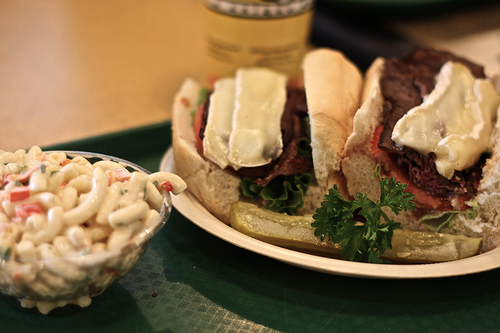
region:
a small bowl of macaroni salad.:
[2, 147, 179, 313]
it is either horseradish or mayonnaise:
[209, 73, 276, 171]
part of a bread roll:
[306, 51, 383, 208]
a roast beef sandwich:
[351, 48, 491, 284]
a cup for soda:
[198, 4, 304, 79]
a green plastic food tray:
[178, 252, 435, 331]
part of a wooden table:
[4, 17, 184, 107]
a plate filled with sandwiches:
[154, 73, 496, 304]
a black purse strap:
[331, 9, 418, 60]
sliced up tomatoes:
[13, 182, 40, 221]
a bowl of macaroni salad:
[6, 146, 168, 305]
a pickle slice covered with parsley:
[246, 205, 478, 258]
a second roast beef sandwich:
[175, 47, 352, 217]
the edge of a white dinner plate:
[153, 145, 497, 322]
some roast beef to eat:
[381, 45, 431, 109]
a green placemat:
[163, 250, 487, 331]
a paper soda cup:
[199, 3, 310, 90]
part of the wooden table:
[3, 4, 173, 112]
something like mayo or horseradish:
[413, 61, 486, 190]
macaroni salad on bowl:
[2, 142, 165, 302]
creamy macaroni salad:
[0, 136, 176, 308]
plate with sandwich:
[181, 46, 496, 262]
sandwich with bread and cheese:
[171, 73, 313, 210]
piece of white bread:
[305, 45, 364, 175]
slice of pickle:
[233, 201, 486, 261]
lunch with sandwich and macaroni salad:
[0, 39, 497, 308]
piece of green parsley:
[314, 177, 419, 263]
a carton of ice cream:
[202, 1, 316, 76]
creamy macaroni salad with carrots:
[5, 162, 131, 244]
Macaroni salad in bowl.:
[1, 138, 173, 322]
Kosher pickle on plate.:
[216, 170, 498, 277]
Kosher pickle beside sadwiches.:
[171, 45, 498, 279]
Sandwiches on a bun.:
[174, 32, 498, 227]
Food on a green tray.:
[0, 42, 499, 331]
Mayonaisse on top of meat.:
[353, 42, 498, 220]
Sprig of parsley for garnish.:
[306, 168, 418, 275]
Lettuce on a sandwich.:
[169, 60, 318, 228]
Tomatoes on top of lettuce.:
[178, 51, 318, 221]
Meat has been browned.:
[349, 32, 499, 217]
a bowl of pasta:
[1, 137, 192, 322]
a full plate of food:
[160, 40, 498, 275]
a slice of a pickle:
[228, 192, 483, 269]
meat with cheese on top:
[380, 38, 498, 195]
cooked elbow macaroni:
[9, 156, 133, 246]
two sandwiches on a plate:
[161, 41, 499, 246]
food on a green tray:
[5, 67, 499, 327]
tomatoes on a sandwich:
[370, 123, 480, 233]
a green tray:
[116, 101, 346, 330]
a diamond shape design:
[128, 279, 355, 331]